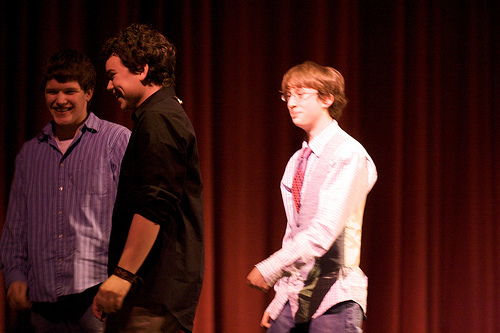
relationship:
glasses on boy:
[279, 86, 328, 101] [243, 60, 379, 331]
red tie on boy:
[289, 144, 311, 215] [243, 60, 379, 331]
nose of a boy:
[287, 89, 303, 111] [224, 45, 391, 332]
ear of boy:
[323, 84, 336, 111] [264, 48, 378, 226]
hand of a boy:
[240, 261, 279, 294] [243, 60, 379, 331]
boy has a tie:
[243, 60, 379, 331] [290, 145, 312, 213]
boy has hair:
[243, 60, 379, 331] [279, 57, 344, 117]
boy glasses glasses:
[243, 60, 379, 331] [282, 87, 311, 99]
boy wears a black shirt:
[86, 26, 211, 332] [106, 85, 204, 332]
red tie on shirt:
[289, 144, 311, 215] [255, 118, 377, 322]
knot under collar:
[299, 145, 324, 162] [304, 126, 329, 155]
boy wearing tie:
[243, 60, 379, 331] [289, 147, 309, 222]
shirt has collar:
[0, 110, 130, 304] [35, 110, 103, 153]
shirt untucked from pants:
[255, 118, 377, 322] [220, 248, 389, 331]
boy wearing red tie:
[243, 60, 379, 331] [287, 142, 311, 222]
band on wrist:
[109, 262, 144, 288] [101, 258, 141, 296]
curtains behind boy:
[0, 0, 499, 331] [0, 47, 131, 330]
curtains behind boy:
[0, 0, 499, 331] [93, 20, 209, 331]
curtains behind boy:
[0, 0, 499, 331] [243, 60, 379, 331]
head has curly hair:
[98, 24, 177, 113] [102, 23, 177, 83]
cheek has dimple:
[115, 74, 144, 98] [114, 83, 128, 96]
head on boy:
[271, 63, 351, 128] [243, 60, 379, 331]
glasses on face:
[279, 86, 328, 101] [281, 87, 324, 132]